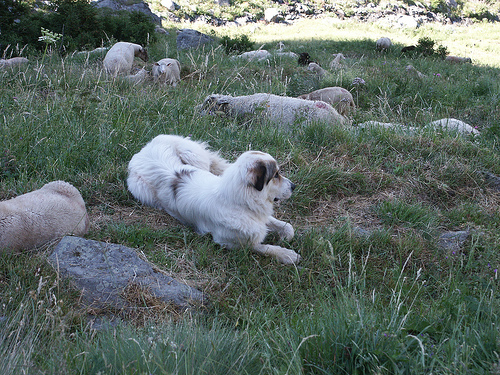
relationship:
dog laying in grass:
[127, 132, 302, 268] [0, 19, 498, 374]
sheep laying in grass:
[0, 178, 93, 254] [0, 19, 498, 374]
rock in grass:
[47, 233, 208, 315] [0, 19, 498, 374]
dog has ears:
[127, 132, 302, 268] [245, 157, 266, 192]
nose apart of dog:
[289, 181, 297, 192] [127, 132, 302, 268]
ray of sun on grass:
[149, 0, 499, 69] [0, 19, 498, 374]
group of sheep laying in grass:
[0, 37, 483, 149] [0, 19, 498, 374]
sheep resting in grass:
[0, 178, 93, 254] [0, 19, 498, 374]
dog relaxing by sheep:
[127, 132, 302, 268] [197, 93, 352, 141]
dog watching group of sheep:
[127, 132, 302, 268] [0, 37, 483, 149]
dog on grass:
[127, 132, 302, 268] [0, 19, 498, 374]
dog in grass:
[127, 132, 302, 268] [0, 19, 498, 374]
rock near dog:
[47, 233, 208, 315] [127, 132, 302, 268]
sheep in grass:
[0, 178, 93, 254] [0, 19, 498, 374]